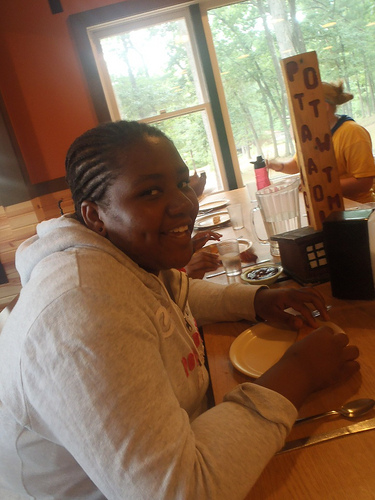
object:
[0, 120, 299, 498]
girl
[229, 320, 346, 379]
plate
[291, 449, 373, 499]
table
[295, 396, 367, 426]
spoon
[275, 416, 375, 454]
knife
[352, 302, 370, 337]
table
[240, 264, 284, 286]
bowl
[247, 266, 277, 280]
sauce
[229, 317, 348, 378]
dish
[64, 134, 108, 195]
corn rows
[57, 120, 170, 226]
hair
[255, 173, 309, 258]
pitcher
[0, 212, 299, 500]
shirt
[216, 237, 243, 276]
cup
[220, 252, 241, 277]
water